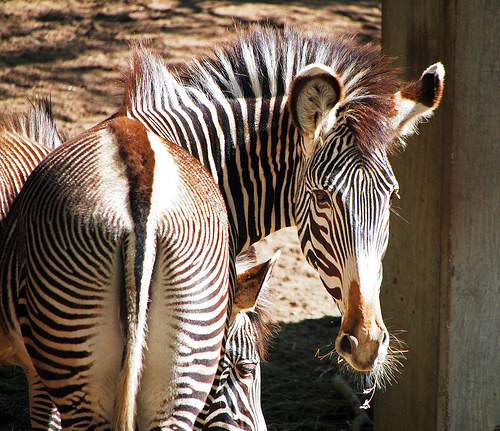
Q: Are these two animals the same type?
A: Yes, all the animals are zebras.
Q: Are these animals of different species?
A: No, all the animals are zebras.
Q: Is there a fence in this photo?
A: No, there are no fences.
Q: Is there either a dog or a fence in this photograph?
A: No, there are no fences or dogs.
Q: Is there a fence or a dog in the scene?
A: No, there are no fences or dogs.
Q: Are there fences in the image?
A: No, there are no fences.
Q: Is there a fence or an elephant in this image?
A: No, there are no fences or elephants.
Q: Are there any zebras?
A: Yes, there is a zebra.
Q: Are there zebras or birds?
A: Yes, there is a zebra.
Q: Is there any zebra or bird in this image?
A: Yes, there is a zebra.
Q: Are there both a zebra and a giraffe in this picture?
A: No, there is a zebra but no giraffes.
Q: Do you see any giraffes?
A: No, there are no giraffes.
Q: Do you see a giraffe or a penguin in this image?
A: No, there are no giraffes or penguins.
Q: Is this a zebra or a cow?
A: This is a zebra.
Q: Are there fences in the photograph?
A: No, there are no fences.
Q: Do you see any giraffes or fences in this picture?
A: No, there are no fences or giraffes.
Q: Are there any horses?
A: No, there are no horses.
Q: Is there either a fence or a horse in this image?
A: No, there are no horses or fences.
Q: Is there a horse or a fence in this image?
A: No, there are no horses or fences.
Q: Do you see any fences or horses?
A: No, there are no horses or fences.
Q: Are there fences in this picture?
A: No, there are no fences.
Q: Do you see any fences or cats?
A: No, there are no fences or cats.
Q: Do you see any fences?
A: No, there are no fences.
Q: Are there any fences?
A: No, there are no fences.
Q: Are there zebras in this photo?
A: Yes, there is a zebra.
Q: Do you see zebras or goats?
A: Yes, there is a zebra.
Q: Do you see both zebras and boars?
A: No, there is a zebra but no boars.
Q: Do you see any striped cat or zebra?
A: Yes, there is a striped zebra.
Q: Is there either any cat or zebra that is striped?
A: Yes, the zebra is striped.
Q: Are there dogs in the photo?
A: No, there are no dogs.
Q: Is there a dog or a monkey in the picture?
A: No, there are no dogs or monkeys.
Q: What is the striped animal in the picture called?
A: The animal is a zebra.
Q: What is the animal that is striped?
A: The animal is a zebra.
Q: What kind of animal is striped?
A: The animal is a zebra.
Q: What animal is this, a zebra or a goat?
A: This is a zebra.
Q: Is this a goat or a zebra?
A: This is a zebra.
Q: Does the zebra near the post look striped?
A: Yes, the zebra is striped.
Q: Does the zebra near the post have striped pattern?
A: Yes, the zebra is striped.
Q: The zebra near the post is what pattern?
A: The zebra is striped.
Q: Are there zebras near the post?
A: Yes, there is a zebra near the post.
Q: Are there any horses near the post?
A: No, there is a zebra near the post.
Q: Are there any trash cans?
A: No, there are no trash cans.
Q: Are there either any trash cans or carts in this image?
A: No, there are no trash cans or carts.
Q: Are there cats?
A: No, there are no cats.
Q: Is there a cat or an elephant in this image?
A: No, there are no cats or elephants.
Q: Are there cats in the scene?
A: No, there are no cats.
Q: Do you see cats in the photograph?
A: No, there are no cats.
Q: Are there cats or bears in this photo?
A: No, there are no cats or bears.